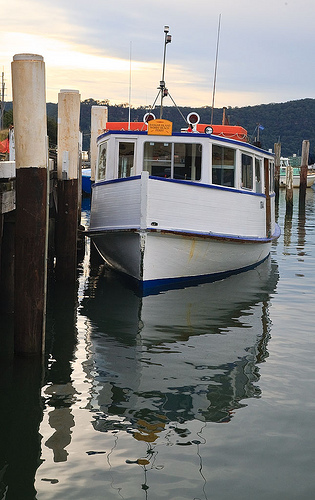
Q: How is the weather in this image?
A: It is cloudy.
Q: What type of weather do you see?
A: It is cloudy.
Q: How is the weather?
A: It is cloudy.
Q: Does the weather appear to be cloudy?
A: Yes, it is cloudy.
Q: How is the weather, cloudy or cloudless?
A: It is cloudy.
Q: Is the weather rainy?
A: No, it is cloudy.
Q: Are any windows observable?
A: Yes, there is a window.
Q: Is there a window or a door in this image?
A: Yes, there is a window.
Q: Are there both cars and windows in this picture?
A: No, there is a window but no cars.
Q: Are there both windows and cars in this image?
A: No, there is a window but no cars.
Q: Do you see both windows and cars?
A: No, there is a window but no cars.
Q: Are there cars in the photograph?
A: No, there are no cars.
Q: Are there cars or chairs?
A: No, there are no cars or chairs.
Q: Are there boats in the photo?
A: Yes, there is a boat.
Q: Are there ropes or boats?
A: Yes, there is a boat.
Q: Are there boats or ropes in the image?
A: Yes, there is a boat.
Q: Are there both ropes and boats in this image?
A: No, there is a boat but no ropes.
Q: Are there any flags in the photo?
A: No, there are no flags.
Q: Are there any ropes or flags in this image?
A: No, there are no flags or ropes.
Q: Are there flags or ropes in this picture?
A: No, there are no flags or ropes.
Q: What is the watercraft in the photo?
A: The watercraft is a boat.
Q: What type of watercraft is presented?
A: The watercraft is a boat.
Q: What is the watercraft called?
A: The watercraft is a boat.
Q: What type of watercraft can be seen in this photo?
A: The watercraft is a boat.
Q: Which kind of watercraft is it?
A: The watercraft is a boat.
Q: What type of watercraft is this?
A: This is a boat.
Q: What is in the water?
A: The boat is in the water.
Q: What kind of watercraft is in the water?
A: The watercraft is a boat.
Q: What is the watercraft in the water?
A: The watercraft is a boat.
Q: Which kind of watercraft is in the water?
A: The watercraft is a boat.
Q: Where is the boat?
A: The boat is in the water.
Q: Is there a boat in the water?
A: Yes, there is a boat in the water.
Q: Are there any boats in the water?
A: Yes, there is a boat in the water.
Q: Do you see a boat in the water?
A: Yes, there is a boat in the water.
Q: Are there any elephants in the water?
A: No, there is a boat in the water.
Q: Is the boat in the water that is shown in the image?
A: Yes, the boat is in the water.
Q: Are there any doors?
A: Yes, there is a door.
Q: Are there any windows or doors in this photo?
A: Yes, there is a door.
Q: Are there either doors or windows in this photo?
A: Yes, there is a door.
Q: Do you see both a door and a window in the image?
A: Yes, there are both a door and a window.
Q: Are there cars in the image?
A: No, there are no cars.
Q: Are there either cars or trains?
A: No, there are no cars or trains.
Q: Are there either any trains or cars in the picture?
A: No, there are no cars or trains.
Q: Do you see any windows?
A: Yes, there are windows.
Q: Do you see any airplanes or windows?
A: Yes, there are windows.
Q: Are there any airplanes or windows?
A: Yes, there are windows.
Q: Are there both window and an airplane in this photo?
A: No, there are windows but no airplanes.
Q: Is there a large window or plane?
A: Yes, there are large windows.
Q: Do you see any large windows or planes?
A: Yes, there are large windows.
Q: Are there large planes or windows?
A: Yes, there are large windows.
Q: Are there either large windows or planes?
A: Yes, there are large windows.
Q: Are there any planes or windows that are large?
A: Yes, the windows are large.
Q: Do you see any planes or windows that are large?
A: Yes, the windows are large.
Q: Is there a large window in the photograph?
A: Yes, there are large windows.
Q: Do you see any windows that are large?
A: Yes, there are windows that are large.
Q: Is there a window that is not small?
A: Yes, there are large windows.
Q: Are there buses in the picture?
A: No, there are no buses.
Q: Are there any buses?
A: No, there are no buses.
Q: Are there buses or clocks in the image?
A: No, there are no buses or clocks.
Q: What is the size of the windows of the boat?
A: The windows are large.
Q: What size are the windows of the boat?
A: The windows are large.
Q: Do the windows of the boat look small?
A: No, the windows are large.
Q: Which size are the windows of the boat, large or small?
A: The windows are large.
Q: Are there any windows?
A: Yes, there is a window.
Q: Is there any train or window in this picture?
A: Yes, there is a window.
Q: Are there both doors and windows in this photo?
A: Yes, there are both a window and a door.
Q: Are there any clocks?
A: No, there are no clocks.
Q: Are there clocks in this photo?
A: No, there are no clocks.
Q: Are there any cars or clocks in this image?
A: No, there are no clocks or cars.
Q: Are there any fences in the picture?
A: No, there are no fences.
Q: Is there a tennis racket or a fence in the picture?
A: No, there are no fences or rackets.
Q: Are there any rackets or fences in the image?
A: No, there are no fences or rackets.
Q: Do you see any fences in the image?
A: No, there are no fences.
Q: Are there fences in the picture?
A: No, there are no fences.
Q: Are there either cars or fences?
A: No, there are no fences or cars.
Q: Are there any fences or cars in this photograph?
A: No, there are no fences or cars.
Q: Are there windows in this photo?
A: Yes, there is a window.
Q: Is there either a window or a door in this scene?
A: Yes, there is a window.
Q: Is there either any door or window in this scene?
A: Yes, there is a window.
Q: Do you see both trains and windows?
A: No, there is a window but no trains.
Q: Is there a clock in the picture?
A: No, there are no clocks.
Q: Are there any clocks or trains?
A: No, there are no clocks or trains.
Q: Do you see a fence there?
A: No, there are no fences.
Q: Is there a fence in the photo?
A: No, there are no fences.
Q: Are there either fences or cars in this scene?
A: No, there are no fences or cars.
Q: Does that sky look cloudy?
A: Yes, the sky is cloudy.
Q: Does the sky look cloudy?
A: Yes, the sky is cloudy.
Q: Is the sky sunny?
A: No, the sky is cloudy.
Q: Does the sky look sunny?
A: No, the sky is cloudy.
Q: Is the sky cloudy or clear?
A: The sky is cloudy.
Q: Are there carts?
A: No, there are no carts.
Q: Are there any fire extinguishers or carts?
A: No, there are no carts or fire extinguishers.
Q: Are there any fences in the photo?
A: No, there are no fences.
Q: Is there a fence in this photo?
A: No, there are no fences.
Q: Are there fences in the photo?
A: No, there are no fences.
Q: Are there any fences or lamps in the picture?
A: No, there are no fences or lamps.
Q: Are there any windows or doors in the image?
A: Yes, there is a window.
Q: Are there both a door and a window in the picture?
A: Yes, there are both a window and a door.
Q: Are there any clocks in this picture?
A: No, there are no clocks.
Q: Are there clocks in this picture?
A: No, there are no clocks.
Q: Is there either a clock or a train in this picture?
A: No, there are no clocks or trains.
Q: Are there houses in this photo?
A: No, there are no houses.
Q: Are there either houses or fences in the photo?
A: No, there are no houses or fences.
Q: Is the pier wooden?
A: Yes, the pier is wooden.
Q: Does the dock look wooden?
A: Yes, the dock is wooden.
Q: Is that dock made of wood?
A: Yes, the dock is made of wood.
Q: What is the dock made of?
A: The dock is made of wood.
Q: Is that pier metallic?
A: No, the pier is wooden.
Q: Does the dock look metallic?
A: No, the dock is wooden.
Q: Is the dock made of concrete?
A: No, the dock is made of wood.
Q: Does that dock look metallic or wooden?
A: The dock is wooden.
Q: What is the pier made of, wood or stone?
A: The pier is made of wood.